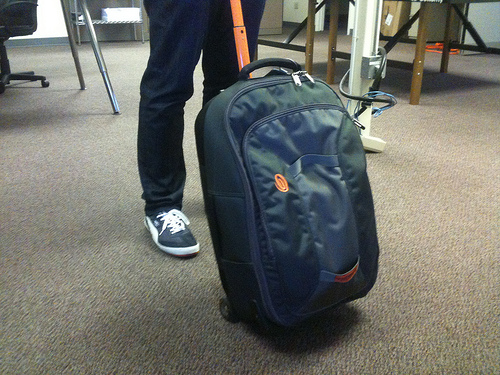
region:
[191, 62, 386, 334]
a backpack being carried around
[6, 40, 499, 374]
the carpet on the ground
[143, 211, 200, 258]
the blue and white tennis shoe the person is wearing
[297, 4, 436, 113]
a bunch of table legs behind the pole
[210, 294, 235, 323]
some wheels attached to the backpack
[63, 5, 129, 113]
the metal legs of the chair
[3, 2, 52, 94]
a black office chair sitting on the side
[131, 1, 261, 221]
the black pants the person is wearing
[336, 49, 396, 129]
wiring attached to the white pole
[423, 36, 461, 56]
a red cord on the ground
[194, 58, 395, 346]
a dark gray suitcase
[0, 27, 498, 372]
a gray carpet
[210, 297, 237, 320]
a black wheel on a suitcase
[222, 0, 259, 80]
an orange handle on a suitcase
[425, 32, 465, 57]
an orange cord on the floor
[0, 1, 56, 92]
a black desk chair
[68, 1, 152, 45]
a white wire shelf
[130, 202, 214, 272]
a dark gray and white shoe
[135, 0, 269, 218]
a pair of navy pants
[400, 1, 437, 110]
a leg of a table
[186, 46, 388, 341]
upright luggage on carpet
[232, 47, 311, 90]
black handle on luggage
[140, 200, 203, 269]
sneaker with white lace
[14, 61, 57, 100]
wheel on office chair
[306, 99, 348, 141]
light reflection on luggage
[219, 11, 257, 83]
orange pole behind luggage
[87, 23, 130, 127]
metal leg on floor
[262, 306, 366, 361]
shadow of luggage on floor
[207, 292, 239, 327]
wheel on bottom of luggage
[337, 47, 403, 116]
black cable around pole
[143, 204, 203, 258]
Black and white sneaker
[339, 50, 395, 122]
Electrical junction box and wires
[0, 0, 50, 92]
Black rolling desk chair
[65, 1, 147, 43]
Metal shelves with white box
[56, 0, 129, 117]
Two slanted metal legs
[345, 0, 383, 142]
White metal support beam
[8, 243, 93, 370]
Grey carpeting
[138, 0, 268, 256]
A person's legs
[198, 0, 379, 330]
A blue rolling suite case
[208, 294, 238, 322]
Castor wheel on carpet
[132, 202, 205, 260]
person's right black shoe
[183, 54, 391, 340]
rolling dark colored bag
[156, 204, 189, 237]
white colored shoe laces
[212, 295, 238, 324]
wheel on a rolling bag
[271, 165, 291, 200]
orange design on a bag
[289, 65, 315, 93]
two zippers on a rolling bag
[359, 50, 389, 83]
electrical box on a post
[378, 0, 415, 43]
cardboard box in the background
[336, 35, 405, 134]
wires wrapped around a pole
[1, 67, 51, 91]
base of an office chair